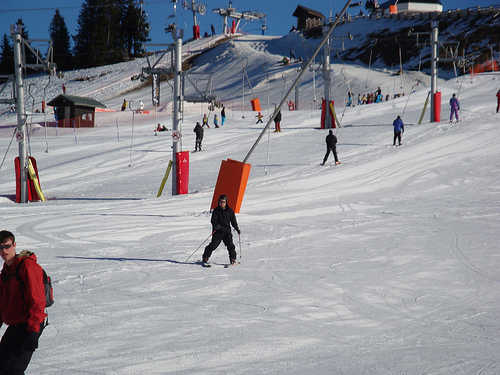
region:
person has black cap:
[207, 191, 235, 209]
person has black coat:
[203, 206, 234, 232]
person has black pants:
[203, 231, 233, 256]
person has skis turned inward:
[195, 256, 244, 279]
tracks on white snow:
[46, 204, 173, 279]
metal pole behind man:
[163, 36, 202, 183]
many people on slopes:
[143, 51, 448, 147]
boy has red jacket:
[0, 251, 53, 323]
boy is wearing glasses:
[0, 234, 15, 244]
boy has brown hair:
[0, 230, 14, 243]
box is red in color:
[169, 149, 202, 199]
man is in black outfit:
[211, 203, 270, 268]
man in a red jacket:
[9, 257, 51, 316]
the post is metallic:
[163, 39, 190, 123]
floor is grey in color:
[304, 254, 435, 348]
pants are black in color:
[10, 328, 38, 374]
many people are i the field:
[176, 35, 381, 130]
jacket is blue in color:
[394, 114, 412, 129]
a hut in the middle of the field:
[51, 88, 109, 142]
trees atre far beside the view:
[98, 19, 135, 57]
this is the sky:
[271, 7, 286, 28]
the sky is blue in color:
[271, 3, 283, 25]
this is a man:
[207, 186, 239, 256]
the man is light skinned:
[3, 247, 19, 252]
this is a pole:
[7, 31, 37, 169]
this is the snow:
[339, 178, 422, 270]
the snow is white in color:
[326, 227, 357, 281]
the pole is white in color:
[173, 41, 185, 65]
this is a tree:
[71, 15, 106, 57]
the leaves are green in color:
[90, 20, 114, 35]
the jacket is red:
[2, 256, 63, 326]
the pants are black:
[7, 326, 37, 371]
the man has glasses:
[3, 232, 64, 374]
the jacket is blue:
[391, 118, 405, 128]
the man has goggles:
[202, 195, 245, 275]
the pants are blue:
[220, 117, 227, 127]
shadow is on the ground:
[70, 247, 189, 268]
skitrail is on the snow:
[386, 247, 436, 277]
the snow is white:
[308, 233, 417, 330]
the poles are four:
[10, 30, 449, 187]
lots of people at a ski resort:
[2, 48, 484, 368]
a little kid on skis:
[178, 194, 247, 266]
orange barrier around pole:
[181, 145, 296, 212]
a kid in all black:
[184, 176, 280, 281]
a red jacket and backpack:
[7, 244, 72, 345]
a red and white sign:
[162, 124, 198, 149]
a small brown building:
[36, 80, 111, 150]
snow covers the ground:
[31, 53, 498, 365]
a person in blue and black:
[383, 108, 434, 162]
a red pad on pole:
[166, 139, 219, 199]